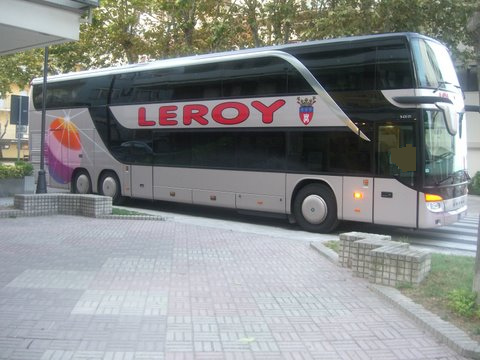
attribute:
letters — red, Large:
[126, 92, 282, 138]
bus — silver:
[25, 27, 471, 228]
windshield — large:
[402, 95, 476, 186]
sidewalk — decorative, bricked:
[4, 217, 462, 353]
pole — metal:
[29, 37, 54, 194]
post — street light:
[31, 52, 46, 185]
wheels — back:
[67, 166, 121, 207]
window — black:
[377, 37, 418, 89]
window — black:
[457, 64, 478, 89]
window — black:
[10, 94, 29, 125]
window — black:
[376, 123, 416, 177]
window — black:
[424, 110, 467, 180]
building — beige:
[467, 95, 478, 125]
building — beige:
[0, 77, 29, 162]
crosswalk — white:
[387, 210, 478, 258]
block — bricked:
[336, 230, 429, 287]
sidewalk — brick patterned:
[0, 214, 480, 360]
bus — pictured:
[24, 58, 456, 250]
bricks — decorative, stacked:
[331, 221, 433, 287]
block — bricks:
[349, 235, 405, 279]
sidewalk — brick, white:
[5, 191, 464, 354]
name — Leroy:
[134, 97, 286, 128]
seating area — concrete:
[340, 225, 434, 302]